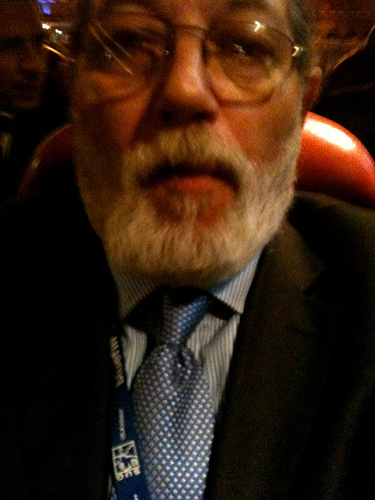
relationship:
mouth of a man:
[132, 150, 245, 196] [2, 1, 364, 496]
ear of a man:
[304, 66, 321, 124] [61, 1, 309, 280]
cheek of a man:
[72, 63, 185, 176] [2, 1, 364, 496]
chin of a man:
[118, 205, 258, 286] [2, 1, 364, 496]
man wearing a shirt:
[2, 1, 375, 500] [13, 182, 374, 497]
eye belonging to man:
[101, 28, 154, 50] [51, 0, 340, 265]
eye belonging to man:
[217, 32, 274, 61] [51, 0, 340, 265]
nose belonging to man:
[160, 64, 226, 105] [2, 1, 364, 496]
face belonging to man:
[72, 1, 317, 273] [2, 1, 364, 496]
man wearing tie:
[2, 1, 364, 496] [131, 291, 214, 498]